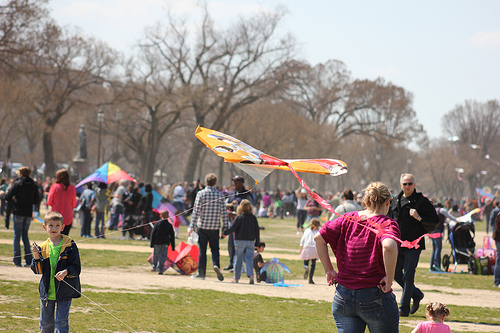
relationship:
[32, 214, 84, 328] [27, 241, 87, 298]
boy wearing coat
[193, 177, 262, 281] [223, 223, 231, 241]
couple holding hands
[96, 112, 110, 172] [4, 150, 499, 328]
post in park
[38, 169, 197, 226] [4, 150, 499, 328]
people in park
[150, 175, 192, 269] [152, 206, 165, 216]
person has head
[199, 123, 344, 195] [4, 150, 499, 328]
kite in park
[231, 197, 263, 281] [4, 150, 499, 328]
woman in park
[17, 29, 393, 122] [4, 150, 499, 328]
trees in park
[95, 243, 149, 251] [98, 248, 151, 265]
dirt in grass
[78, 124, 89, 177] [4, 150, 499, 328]
statue in park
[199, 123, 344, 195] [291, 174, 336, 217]
kite has tail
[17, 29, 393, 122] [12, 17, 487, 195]
trees in background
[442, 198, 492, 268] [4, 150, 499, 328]
stroller in park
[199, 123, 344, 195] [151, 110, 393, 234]
kite i air